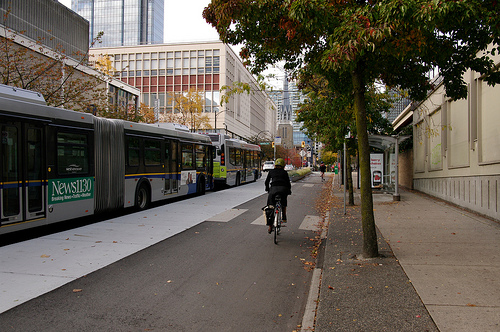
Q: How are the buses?
A: Parked.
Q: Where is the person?
A: On bike.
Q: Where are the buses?
A: On street.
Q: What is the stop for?
A: Bus.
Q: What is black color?
A: Street.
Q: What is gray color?
A: Bus.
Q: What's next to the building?
A: Sidewalk.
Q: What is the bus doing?
A: Parked.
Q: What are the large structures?
A: Buildings.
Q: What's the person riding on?
A: Bike.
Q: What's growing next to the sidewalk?
A: Trees.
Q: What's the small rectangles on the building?
A: Windows.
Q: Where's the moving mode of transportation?
A: Bike.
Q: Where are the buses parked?
A: On road.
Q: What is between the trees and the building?
A: Sidewalk.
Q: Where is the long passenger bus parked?
A: STret.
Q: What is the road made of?
A: Concrete.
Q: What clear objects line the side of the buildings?
A: Windows.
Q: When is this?
A: Daytime.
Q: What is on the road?
A: White lines.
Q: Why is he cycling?
A: Travelling.